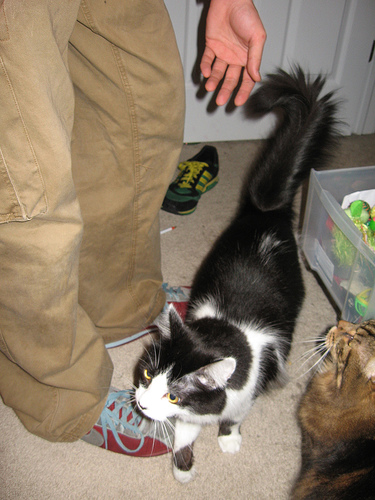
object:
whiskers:
[134, 336, 167, 378]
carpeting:
[2, 131, 373, 498]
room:
[2, 0, 373, 498]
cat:
[307, 308, 373, 488]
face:
[125, 303, 239, 427]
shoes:
[65, 387, 169, 472]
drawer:
[301, 162, 373, 327]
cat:
[137, 67, 350, 484]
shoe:
[159, 144, 219, 215]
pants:
[2, 6, 191, 424]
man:
[0, 0, 266, 456]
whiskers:
[135, 426, 182, 469]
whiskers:
[110, 374, 136, 416]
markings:
[123, 360, 193, 431]